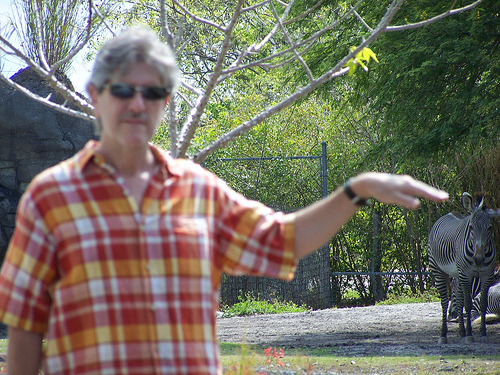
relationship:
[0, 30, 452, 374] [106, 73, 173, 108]
man wearing sunglasses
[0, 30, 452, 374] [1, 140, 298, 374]
man wearing orange-red shirt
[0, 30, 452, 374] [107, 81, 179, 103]
man wearing sunglasses.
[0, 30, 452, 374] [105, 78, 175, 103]
man wearing glasses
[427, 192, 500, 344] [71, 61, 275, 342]
zebra staring at person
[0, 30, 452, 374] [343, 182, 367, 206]
man wears watch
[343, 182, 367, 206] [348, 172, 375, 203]
watch on left wrist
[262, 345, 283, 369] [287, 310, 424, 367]
flowers on ground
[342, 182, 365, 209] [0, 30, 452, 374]
watch band worn by man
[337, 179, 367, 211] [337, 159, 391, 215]
watch on wrist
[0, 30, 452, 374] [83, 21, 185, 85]
man has gray hair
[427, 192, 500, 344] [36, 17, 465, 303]
zebra right man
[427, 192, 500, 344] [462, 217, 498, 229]
zebra has eyes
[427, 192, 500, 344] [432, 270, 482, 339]
zebra has legs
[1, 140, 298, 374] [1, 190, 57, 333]
orange-red shirt has sleeve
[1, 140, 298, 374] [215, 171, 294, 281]
orange-red shirt has sleeve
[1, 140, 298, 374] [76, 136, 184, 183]
orange-red shirt has collar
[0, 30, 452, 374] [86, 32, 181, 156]
man has moustache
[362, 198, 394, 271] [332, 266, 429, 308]
tree outside gate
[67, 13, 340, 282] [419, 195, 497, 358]
man points zebra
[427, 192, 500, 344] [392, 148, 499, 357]
zebra under shade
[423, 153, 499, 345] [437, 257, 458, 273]
zebra has belly